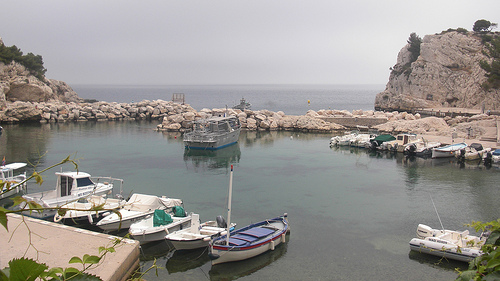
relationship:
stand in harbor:
[171, 90, 189, 106] [0, 87, 498, 280]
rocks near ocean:
[2, 99, 421, 157] [71, 86, 384, 116]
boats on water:
[1, 160, 291, 267] [3, 122, 499, 280]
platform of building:
[0, 212, 145, 281] [0, 212, 140, 280]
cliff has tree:
[377, 30, 498, 116] [474, 17, 500, 35]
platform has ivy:
[0, 212, 145, 281] [3, 259, 110, 279]